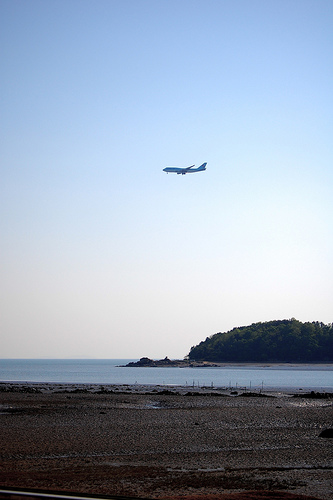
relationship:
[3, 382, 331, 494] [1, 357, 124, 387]
beach by ocean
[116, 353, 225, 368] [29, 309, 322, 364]
rocks in distance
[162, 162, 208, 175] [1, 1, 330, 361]
airliner in sky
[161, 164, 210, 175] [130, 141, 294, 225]
airliner in flight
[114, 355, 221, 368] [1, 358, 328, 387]
land surrounded by water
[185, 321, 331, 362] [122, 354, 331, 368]
trees on land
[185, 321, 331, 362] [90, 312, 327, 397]
trees in background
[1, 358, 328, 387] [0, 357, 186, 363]
water in horizon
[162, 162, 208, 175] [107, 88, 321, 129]
airliner in sky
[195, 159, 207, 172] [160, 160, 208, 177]
tail of a airplane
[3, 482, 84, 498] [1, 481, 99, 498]
line on surface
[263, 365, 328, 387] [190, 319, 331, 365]
water between land mass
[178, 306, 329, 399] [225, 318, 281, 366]
mass of trees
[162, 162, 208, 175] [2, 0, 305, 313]
airliner in sky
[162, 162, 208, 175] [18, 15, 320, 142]
airliner in sky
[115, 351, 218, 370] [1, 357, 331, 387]
island in ocean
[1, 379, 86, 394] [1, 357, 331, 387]
sand near ocean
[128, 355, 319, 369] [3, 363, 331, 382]
beach across ocean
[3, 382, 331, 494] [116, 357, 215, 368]
beach on island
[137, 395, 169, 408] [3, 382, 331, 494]
water puddle on beach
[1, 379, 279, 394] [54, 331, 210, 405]
sand on beach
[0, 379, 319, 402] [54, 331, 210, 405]
grass on beach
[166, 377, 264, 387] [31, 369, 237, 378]
fence near water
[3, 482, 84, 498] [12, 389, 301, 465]
line by beach